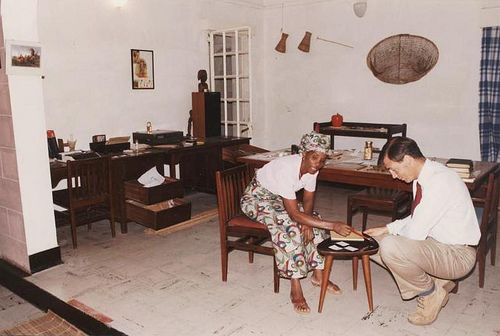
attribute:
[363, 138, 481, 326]
man — examining, crouched, bending, kneeling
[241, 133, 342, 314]
woman — examining, sitting, black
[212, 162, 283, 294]
chair — wooden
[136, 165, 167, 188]
paper — white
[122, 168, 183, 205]
drawer — open, wooden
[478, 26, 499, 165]
curtain — blue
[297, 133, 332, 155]
bonnet — floral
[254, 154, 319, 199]
shirt — white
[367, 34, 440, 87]
fan — large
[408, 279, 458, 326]
boots — tan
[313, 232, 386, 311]
table — small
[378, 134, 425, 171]
hair — brown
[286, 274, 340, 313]
feet — bare